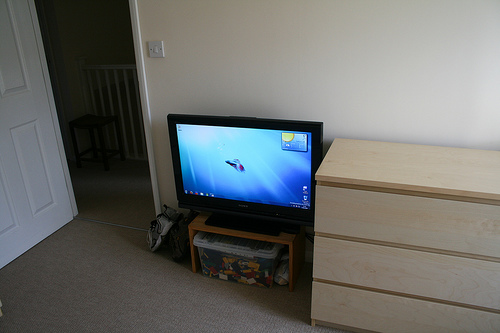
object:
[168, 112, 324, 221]
tv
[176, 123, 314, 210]
screen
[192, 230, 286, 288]
container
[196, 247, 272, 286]
legos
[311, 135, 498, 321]
dresser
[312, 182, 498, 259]
drawer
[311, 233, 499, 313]
drawer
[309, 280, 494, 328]
drawer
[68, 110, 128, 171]
stool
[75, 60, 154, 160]
railing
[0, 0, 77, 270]
door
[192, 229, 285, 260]
lid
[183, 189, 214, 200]
icons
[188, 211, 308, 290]
table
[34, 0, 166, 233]
doorway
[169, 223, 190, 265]
shoe